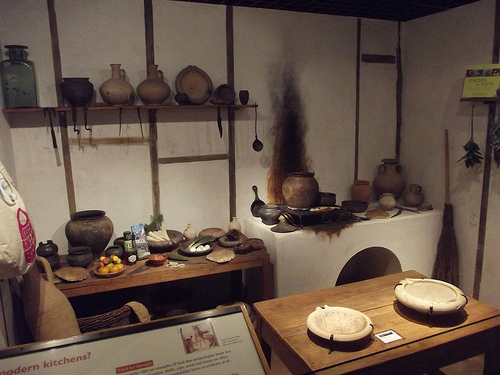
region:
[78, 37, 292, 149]
plenty pots on shelf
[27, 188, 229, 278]
plenty pots on shelf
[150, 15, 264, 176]
plenty pots on shelf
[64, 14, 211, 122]
plenty pots on shelf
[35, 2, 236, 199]
plenty pots on shelf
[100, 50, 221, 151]
plenty pots on shelf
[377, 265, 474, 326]
the pie on the right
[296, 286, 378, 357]
the pie on the left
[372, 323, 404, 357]
the sticker between the pies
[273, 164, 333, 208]
the large pot with a fire stain behind it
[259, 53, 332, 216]
a fire stain on the wall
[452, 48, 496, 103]
a yellow book on a shelf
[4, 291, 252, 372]
a sign with information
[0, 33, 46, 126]
a glass jar on the left of the shelf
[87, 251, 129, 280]
yellow items on a plate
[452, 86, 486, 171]
an item hanging below the yellow sign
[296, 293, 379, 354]
the bowl in the light brown color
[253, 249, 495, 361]
the wooden table with two bowels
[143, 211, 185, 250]
the white color carrot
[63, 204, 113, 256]
the black color pot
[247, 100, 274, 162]
the black color handle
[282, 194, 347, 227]
the black color stove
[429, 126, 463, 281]
the brown color sweeper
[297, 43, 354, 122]
the white color wall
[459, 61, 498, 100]
the photo frame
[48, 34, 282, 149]
the different color pots arranged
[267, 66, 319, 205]
black smoke stain on the wall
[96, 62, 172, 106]
clay jars sitting on a shelf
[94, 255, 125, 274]
veggies sitting in a small saucer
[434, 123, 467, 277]
old straw broom sitting against wall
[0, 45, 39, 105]
glass bottle sitting on shelf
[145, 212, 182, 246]
parsnips sitting in a metal bowl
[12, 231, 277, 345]
small wooden table sitting against wall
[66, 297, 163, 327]
huge basket sitting under wooden table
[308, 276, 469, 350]
clay plates sitting on wooden table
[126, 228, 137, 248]
spice jars sitting on wooden table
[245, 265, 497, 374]
a table is wood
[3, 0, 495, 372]
display of antiquities in a museum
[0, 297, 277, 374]
board to describe the artifacts on display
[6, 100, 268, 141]
a wood shelf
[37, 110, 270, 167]
kitchen utensils hang from shelf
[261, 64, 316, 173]
black spot on white wall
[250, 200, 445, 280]
a white rudimentary kitchen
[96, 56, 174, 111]
two vases on a shelf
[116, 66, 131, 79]
handle of a vase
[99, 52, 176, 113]
vases are made of ceramics